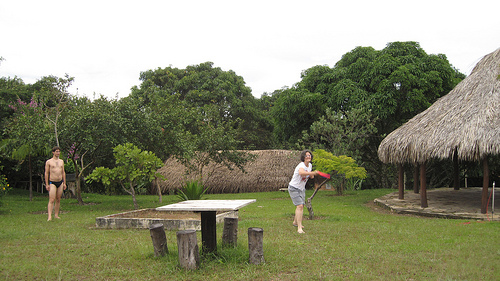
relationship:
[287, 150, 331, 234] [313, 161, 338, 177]
person with frisbee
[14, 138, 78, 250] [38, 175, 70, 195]
man in speedo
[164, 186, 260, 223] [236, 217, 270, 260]
table with stump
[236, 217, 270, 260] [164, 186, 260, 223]
stump around table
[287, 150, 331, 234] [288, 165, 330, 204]
person in suit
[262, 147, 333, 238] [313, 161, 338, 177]
person throwing frisbee